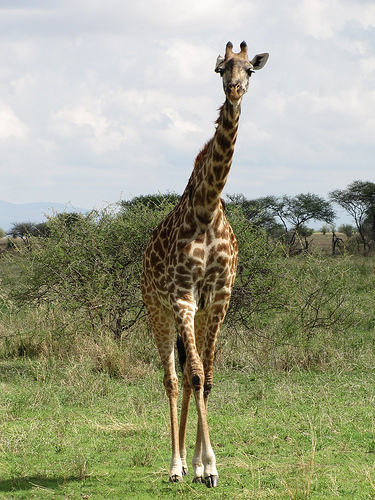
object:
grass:
[3, 390, 153, 499]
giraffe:
[139, 39, 269, 490]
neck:
[191, 95, 241, 232]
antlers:
[225, 41, 233, 54]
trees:
[0, 194, 278, 372]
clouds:
[0, 0, 156, 111]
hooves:
[169, 474, 184, 483]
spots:
[153, 270, 162, 280]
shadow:
[0, 462, 195, 495]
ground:
[0, 233, 374, 500]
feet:
[204, 464, 221, 489]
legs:
[140, 273, 183, 483]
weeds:
[0, 329, 45, 363]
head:
[214, 40, 270, 107]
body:
[138, 195, 242, 321]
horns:
[240, 40, 248, 53]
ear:
[249, 52, 270, 71]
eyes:
[218, 68, 225, 78]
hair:
[194, 96, 228, 169]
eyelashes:
[249, 69, 255, 74]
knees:
[188, 363, 205, 392]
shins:
[169, 394, 180, 456]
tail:
[176, 326, 186, 371]